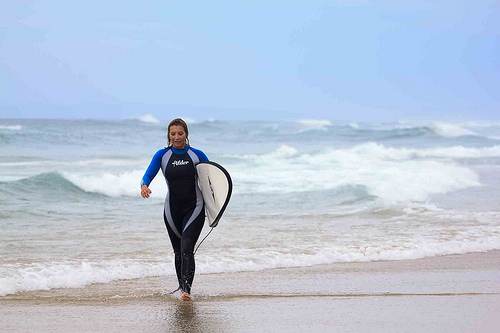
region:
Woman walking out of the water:
[141, 117, 212, 302]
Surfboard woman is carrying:
[191, 161, 232, 228]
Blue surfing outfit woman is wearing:
[141, 145, 209, 293]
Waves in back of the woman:
[1, 112, 497, 202]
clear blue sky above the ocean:
[1, 0, 498, 125]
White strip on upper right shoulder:
[161, 149, 173, 171]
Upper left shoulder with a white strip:
[184, 148, 203, 165]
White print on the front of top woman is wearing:
[169, 157, 187, 164]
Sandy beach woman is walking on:
[0, 250, 499, 330]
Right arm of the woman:
[133, 145, 160, 185]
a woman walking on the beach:
[141, 117, 213, 300]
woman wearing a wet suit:
[141, 145, 213, 290]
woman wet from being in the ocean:
[142, 118, 213, 293]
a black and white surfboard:
[194, 157, 232, 225]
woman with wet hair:
[167, 117, 192, 150]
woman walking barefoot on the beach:
[178, 290, 192, 303]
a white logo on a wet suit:
[171, 156, 189, 168]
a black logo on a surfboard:
[206, 174, 217, 204]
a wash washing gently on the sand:
[1, 220, 499, 290]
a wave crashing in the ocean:
[3, 143, 498, 212]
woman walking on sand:
[131, 116, 229, 314]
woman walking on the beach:
[117, 105, 245, 315]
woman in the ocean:
[105, 116, 239, 305]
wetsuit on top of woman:
[137, 146, 214, 293]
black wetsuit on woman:
[122, 148, 219, 317]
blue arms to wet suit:
[137, 152, 160, 194]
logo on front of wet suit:
[165, 153, 190, 170]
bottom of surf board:
[189, 170, 229, 214]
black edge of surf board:
[215, 168, 236, 192]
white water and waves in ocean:
[322, 117, 437, 214]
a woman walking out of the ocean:
[145, 96, 217, 311]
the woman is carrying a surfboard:
[131, 116, 228, 216]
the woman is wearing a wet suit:
[131, 117, 211, 297]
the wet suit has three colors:
[140, 120, 215, 297]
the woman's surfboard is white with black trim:
[182, 155, 232, 235]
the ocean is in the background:
[16, 112, 481, 226]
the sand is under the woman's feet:
[38, 248, 482, 326]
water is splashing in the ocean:
[298, 133, 438, 203]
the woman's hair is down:
[163, 120, 203, 146]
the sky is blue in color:
[20, 8, 483, 94]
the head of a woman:
[154, 93, 202, 188]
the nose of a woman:
[167, 132, 184, 147]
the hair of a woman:
[158, 114, 203, 154]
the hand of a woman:
[127, 183, 156, 240]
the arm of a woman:
[119, 137, 169, 199]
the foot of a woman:
[159, 273, 241, 318]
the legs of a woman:
[143, 185, 248, 306]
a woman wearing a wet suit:
[129, 101, 277, 305]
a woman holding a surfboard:
[96, 67, 324, 281]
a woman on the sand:
[115, 112, 280, 307]